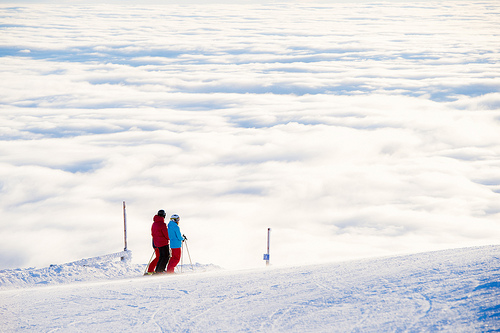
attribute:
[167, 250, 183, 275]
pants — red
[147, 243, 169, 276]
pants — black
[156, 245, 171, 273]
pants — black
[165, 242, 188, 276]
pants — red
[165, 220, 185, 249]
jacket — blue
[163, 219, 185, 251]
coat — blue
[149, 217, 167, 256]
jacket — blue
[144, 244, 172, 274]
ski pants — black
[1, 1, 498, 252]
clouds — large, thick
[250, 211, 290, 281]
poles — skinny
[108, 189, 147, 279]
poles — skinny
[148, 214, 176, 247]
coat — red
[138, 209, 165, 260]
jacket — red, sleeved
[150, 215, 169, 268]
jacket — red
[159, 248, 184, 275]
pants — red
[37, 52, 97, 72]
sky — blue